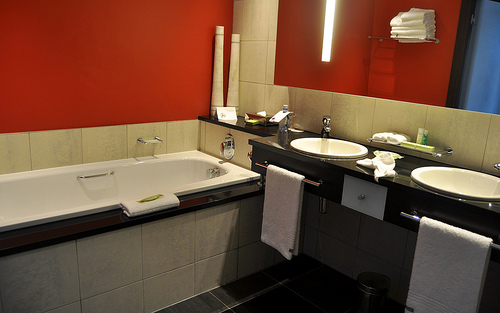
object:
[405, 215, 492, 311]
towel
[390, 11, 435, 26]
towel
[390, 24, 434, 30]
towel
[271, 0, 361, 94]
doll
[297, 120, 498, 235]
table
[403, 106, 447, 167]
ground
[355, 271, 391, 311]
garbage can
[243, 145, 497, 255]
cabinet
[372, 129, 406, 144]
washrags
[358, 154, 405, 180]
washrags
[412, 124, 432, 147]
toiletries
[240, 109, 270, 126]
toiletries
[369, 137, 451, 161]
shelf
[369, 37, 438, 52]
shelf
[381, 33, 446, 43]
towels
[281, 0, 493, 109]
mirror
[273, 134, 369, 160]
sink cabinet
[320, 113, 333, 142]
faucet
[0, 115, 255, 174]
tiling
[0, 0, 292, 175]
wall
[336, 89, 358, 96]
edge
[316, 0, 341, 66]
light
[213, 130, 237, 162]
faucet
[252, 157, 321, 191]
rack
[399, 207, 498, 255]
rack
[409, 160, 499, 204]
sink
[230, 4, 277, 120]
wall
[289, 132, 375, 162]
basin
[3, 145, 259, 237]
bath tub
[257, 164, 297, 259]
towell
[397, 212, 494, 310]
towell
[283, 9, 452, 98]
wall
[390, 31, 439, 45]
wall rack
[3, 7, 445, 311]
bathroom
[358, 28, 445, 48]
shelf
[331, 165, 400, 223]
drawer